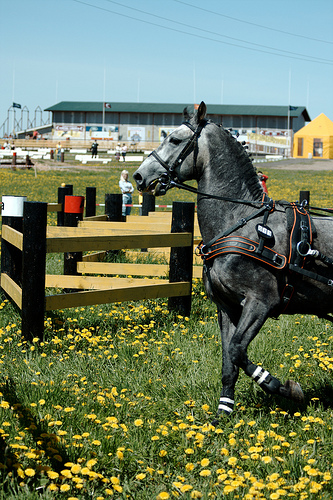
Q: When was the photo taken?
A: Daytime.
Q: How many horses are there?
A: One.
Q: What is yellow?
A: Flowers.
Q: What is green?
A: Grass.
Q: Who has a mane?
A: A horse.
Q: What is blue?
A: Sky.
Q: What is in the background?
A: A building.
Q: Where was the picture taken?
A: In a field.